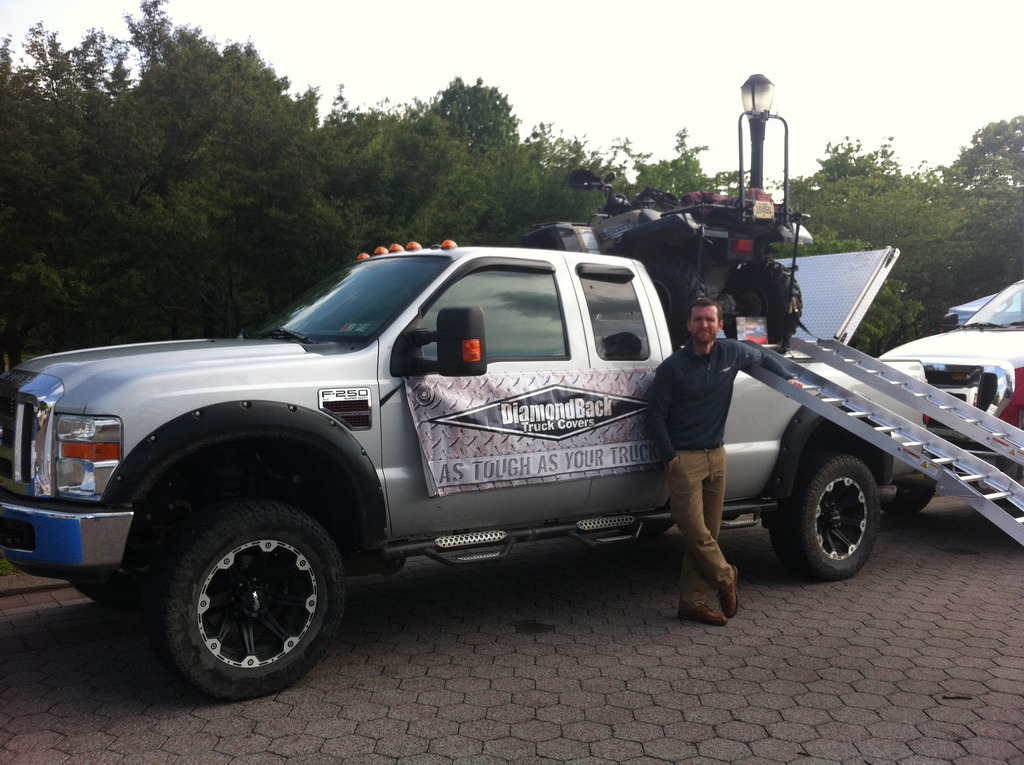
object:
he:
[647, 297, 803, 627]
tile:
[337, 701, 389, 722]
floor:
[0, 492, 1024, 764]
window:
[573, 262, 652, 363]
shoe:
[715, 565, 737, 619]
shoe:
[677, 600, 727, 625]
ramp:
[737, 337, 1024, 550]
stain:
[506, 619, 556, 635]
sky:
[0, 0, 1024, 202]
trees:
[774, 120, 1024, 359]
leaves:
[887, 137, 893, 143]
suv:
[874, 282, 1024, 479]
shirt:
[647, 338, 795, 463]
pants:
[666, 446, 735, 615]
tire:
[150, 494, 348, 701]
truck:
[0, 242, 907, 705]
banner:
[402, 366, 667, 499]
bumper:
[0, 478, 135, 570]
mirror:
[389, 306, 487, 378]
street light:
[740, 75, 775, 193]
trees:
[0, 0, 381, 359]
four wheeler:
[518, 73, 814, 354]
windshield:
[244, 252, 457, 356]